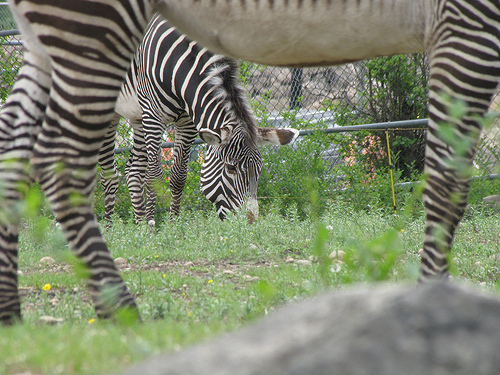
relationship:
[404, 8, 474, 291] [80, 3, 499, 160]
leg on front ot zebra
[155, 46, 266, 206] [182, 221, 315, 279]
zebra eating grass